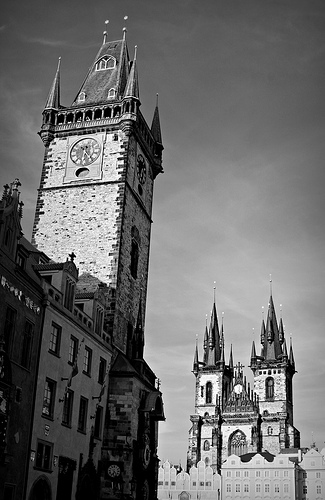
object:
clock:
[107, 464, 121, 479]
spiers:
[102, 19, 110, 44]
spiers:
[122, 15, 129, 40]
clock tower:
[29, 12, 167, 359]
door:
[227, 428, 249, 460]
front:
[187, 272, 288, 472]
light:
[123, 14, 129, 21]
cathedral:
[186, 270, 301, 472]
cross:
[233, 361, 245, 377]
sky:
[0, 0, 325, 460]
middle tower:
[220, 361, 259, 470]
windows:
[226, 483, 232, 494]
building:
[221, 449, 300, 499]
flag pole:
[61, 335, 86, 408]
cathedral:
[0, 5, 168, 500]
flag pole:
[94, 350, 117, 418]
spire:
[213, 278, 217, 304]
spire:
[268, 272, 274, 298]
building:
[29, 15, 165, 356]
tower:
[186, 279, 234, 474]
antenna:
[213, 280, 216, 303]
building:
[185, 277, 234, 475]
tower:
[245, 267, 297, 453]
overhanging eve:
[144, 389, 166, 421]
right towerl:
[246, 271, 302, 461]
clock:
[135, 153, 147, 186]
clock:
[69, 136, 102, 167]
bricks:
[119, 394, 128, 401]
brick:
[30, 134, 129, 338]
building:
[99, 285, 166, 500]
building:
[249, 272, 301, 454]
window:
[48, 319, 63, 359]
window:
[68, 332, 80, 369]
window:
[82, 344, 93, 378]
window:
[41, 375, 58, 423]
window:
[61, 386, 75, 430]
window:
[129, 237, 140, 282]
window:
[75, 166, 90, 178]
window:
[264, 375, 274, 402]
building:
[25, 247, 116, 500]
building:
[0, 177, 48, 500]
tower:
[219, 360, 260, 475]